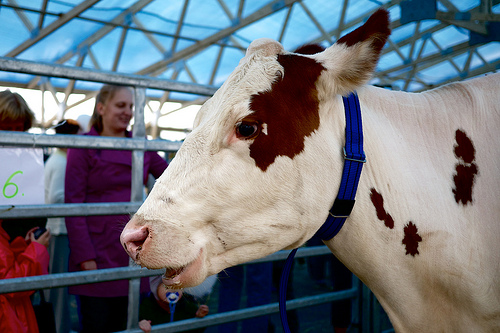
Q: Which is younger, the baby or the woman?
A: The baby is younger than the woman.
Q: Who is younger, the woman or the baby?
A: The baby is younger than the woman.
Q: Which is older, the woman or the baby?
A: The woman is older than the baby.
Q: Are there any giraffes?
A: No, there are no giraffes.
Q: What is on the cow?
A: The spots are on the cow.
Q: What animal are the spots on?
A: The spots are on the cow.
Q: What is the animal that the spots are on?
A: The animal is a cow.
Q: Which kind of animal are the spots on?
A: The spots are on the cow.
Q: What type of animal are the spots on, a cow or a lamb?
A: The spots are on a cow.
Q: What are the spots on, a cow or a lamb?
A: The spots are on a cow.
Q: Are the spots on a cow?
A: Yes, the spots are on a cow.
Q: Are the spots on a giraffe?
A: No, the spots are on a cow.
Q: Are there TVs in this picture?
A: No, there are no tvs.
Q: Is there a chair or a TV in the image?
A: No, there are no televisions or chairs.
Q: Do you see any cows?
A: Yes, there is a cow.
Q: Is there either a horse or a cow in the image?
A: Yes, there is a cow.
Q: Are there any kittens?
A: No, there are no kittens.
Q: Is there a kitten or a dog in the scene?
A: No, there are no kittens or dogs.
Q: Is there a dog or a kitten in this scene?
A: No, there are no kittens or dogs.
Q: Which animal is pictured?
A: The animal is a cow.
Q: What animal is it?
A: The animal is a cow.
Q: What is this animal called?
A: This is a cow.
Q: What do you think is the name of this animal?
A: This is a cow.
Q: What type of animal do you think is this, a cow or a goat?
A: This is a cow.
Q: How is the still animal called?
A: The animal is a cow.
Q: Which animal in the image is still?
A: The animal is a cow.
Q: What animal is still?
A: The animal is a cow.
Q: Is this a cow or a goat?
A: This is a cow.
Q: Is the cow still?
A: Yes, the cow is still.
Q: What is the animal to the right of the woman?
A: The animal is a cow.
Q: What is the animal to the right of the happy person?
A: The animal is a cow.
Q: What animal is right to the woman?
A: The animal is a cow.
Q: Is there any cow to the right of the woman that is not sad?
A: Yes, there is a cow to the right of the woman.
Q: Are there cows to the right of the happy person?
A: Yes, there is a cow to the right of the woman.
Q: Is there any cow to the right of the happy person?
A: Yes, there is a cow to the right of the woman.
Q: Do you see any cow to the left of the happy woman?
A: No, the cow is to the right of the woman.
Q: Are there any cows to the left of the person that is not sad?
A: No, the cow is to the right of the woman.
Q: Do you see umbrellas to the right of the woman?
A: No, there is a cow to the right of the woman.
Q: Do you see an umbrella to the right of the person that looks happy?
A: No, there is a cow to the right of the woman.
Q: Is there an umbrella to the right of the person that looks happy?
A: No, there is a cow to the right of the woman.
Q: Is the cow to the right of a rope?
A: No, the cow is to the right of a woman.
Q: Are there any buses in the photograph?
A: No, there are no buses.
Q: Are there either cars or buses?
A: No, there are no buses or cars.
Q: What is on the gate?
A: The sign is on the gate.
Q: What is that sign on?
A: The sign is on the gate.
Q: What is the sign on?
A: The sign is on the gate.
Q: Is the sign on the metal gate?
A: Yes, the sign is on the gate.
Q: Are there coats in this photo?
A: Yes, there is a coat.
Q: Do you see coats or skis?
A: Yes, there is a coat.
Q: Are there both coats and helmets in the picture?
A: No, there is a coat but no helmets.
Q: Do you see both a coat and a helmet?
A: No, there is a coat but no helmets.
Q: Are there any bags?
A: No, there are no bags.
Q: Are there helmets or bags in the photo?
A: No, there are no bags or helmets.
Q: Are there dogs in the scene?
A: No, there are no dogs.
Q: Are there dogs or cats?
A: No, there are no dogs or cats.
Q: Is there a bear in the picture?
A: No, there are no bears.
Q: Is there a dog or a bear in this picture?
A: No, there are no bears or dogs.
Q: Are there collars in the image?
A: Yes, there is a collar.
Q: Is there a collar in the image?
A: Yes, there is a collar.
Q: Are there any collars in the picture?
A: Yes, there is a collar.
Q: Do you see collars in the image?
A: Yes, there is a collar.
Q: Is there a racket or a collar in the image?
A: Yes, there is a collar.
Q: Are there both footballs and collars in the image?
A: No, there is a collar but no footballs.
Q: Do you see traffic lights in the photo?
A: No, there are no traffic lights.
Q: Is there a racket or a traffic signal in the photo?
A: No, there are no traffic lights or rackets.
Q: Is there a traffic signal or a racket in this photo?
A: No, there are no traffic lights or rackets.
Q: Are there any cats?
A: No, there are no cats.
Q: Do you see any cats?
A: No, there are no cats.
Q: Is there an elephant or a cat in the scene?
A: No, there are no cats or elephants.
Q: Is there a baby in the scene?
A: Yes, there is a baby.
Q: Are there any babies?
A: Yes, there is a baby.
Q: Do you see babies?
A: Yes, there is a baby.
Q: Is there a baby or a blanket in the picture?
A: Yes, there is a baby.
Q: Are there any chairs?
A: No, there are no chairs.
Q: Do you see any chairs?
A: No, there are no chairs.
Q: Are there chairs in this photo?
A: No, there are no chairs.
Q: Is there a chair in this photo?
A: No, there are no chairs.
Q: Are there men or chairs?
A: No, there are no chairs or men.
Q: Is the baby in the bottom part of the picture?
A: Yes, the baby is in the bottom of the image.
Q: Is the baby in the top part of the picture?
A: No, the baby is in the bottom of the image.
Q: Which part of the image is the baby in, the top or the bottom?
A: The baby is in the bottom of the image.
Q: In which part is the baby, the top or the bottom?
A: The baby is in the bottom of the image.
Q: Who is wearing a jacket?
A: The baby is wearing a jacket.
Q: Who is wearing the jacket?
A: The baby is wearing a jacket.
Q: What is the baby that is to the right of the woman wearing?
A: The baby is wearing a jacket.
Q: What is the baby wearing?
A: The baby is wearing a jacket.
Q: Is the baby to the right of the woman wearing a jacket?
A: Yes, the baby is wearing a jacket.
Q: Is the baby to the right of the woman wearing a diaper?
A: No, the baby is wearing a jacket.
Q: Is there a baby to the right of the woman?
A: Yes, there is a baby to the right of the woman.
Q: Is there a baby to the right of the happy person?
A: Yes, there is a baby to the right of the woman.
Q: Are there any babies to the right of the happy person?
A: Yes, there is a baby to the right of the woman.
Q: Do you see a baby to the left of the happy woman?
A: No, the baby is to the right of the woman.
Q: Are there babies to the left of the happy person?
A: No, the baby is to the right of the woman.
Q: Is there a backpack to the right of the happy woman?
A: No, there is a baby to the right of the woman.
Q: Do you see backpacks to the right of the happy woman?
A: No, there is a baby to the right of the woman.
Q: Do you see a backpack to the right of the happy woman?
A: No, there is a baby to the right of the woman.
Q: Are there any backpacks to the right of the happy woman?
A: No, there is a baby to the right of the woman.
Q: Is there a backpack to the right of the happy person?
A: No, there is a baby to the right of the woman.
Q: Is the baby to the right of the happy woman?
A: Yes, the baby is to the right of the woman.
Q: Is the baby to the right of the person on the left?
A: Yes, the baby is to the right of the woman.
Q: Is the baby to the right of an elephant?
A: No, the baby is to the right of the woman.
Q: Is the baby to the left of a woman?
A: No, the baby is to the right of a woman.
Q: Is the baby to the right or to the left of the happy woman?
A: The baby is to the right of the woman.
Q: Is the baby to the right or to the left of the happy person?
A: The baby is to the right of the woman.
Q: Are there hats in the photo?
A: Yes, there is a hat.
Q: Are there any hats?
A: Yes, there is a hat.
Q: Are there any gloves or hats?
A: Yes, there is a hat.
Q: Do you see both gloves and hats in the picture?
A: No, there is a hat but no gloves.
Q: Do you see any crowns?
A: No, there are no crowns.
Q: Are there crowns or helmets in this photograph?
A: No, there are no crowns or helmets.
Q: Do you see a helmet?
A: No, there are no helmets.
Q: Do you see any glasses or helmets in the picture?
A: No, there are no helmets or glasses.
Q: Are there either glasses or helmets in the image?
A: No, there are no helmets or glasses.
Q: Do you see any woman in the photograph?
A: Yes, there is a woman.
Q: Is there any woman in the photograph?
A: Yes, there is a woman.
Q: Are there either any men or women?
A: Yes, there is a woman.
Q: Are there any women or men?
A: Yes, there is a woman.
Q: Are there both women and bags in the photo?
A: No, there is a woman but no bags.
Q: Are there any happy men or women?
A: Yes, there is a happy woman.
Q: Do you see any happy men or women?
A: Yes, there is a happy woman.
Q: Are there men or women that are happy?
A: Yes, the woman is happy.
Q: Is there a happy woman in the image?
A: Yes, there is a happy woman.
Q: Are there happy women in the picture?
A: Yes, there is a happy woman.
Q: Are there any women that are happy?
A: Yes, there is a woman that is happy.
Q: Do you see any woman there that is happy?
A: Yes, there is a woman that is happy.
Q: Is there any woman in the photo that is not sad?
A: Yes, there is a happy woman.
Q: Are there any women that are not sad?
A: Yes, there is a happy woman.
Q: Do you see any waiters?
A: No, there are no waiters.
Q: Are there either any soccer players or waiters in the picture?
A: No, there are no waiters or soccer players.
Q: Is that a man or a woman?
A: That is a woman.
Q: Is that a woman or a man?
A: That is a woman.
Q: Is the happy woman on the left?
A: Yes, the woman is on the left of the image.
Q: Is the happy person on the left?
A: Yes, the woman is on the left of the image.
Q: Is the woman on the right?
A: No, the woman is on the left of the image.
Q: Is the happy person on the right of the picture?
A: No, the woman is on the left of the image.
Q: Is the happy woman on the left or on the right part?
A: The woman is on the left of the image.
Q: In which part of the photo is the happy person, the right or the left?
A: The woman is on the left of the image.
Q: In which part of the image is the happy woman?
A: The woman is on the left of the image.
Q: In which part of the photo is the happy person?
A: The woman is on the left of the image.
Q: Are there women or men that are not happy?
A: No, there is a woman but she is happy.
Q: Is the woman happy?
A: Yes, the woman is happy.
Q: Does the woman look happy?
A: Yes, the woman is happy.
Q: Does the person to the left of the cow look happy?
A: Yes, the woman is happy.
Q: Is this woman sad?
A: No, the woman is happy.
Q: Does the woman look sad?
A: No, the woman is happy.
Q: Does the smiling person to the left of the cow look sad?
A: No, the woman is happy.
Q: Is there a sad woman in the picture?
A: No, there is a woman but she is happy.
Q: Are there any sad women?
A: No, there is a woman but she is happy.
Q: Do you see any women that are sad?
A: No, there is a woman but she is happy.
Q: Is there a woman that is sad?
A: No, there is a woman but she is happy.